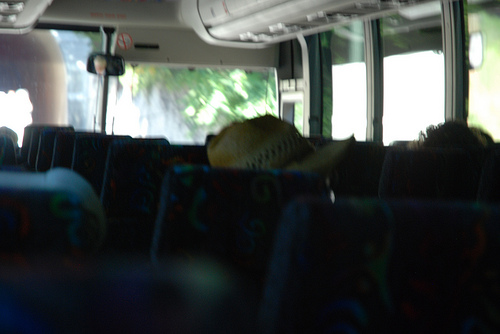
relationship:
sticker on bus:
[112, 30, 137, 54] [1, 1, 500, 331]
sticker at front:
[112, 30, 137, 54] [1, 1, 283, 146]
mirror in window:
[82, 23, 131, 81] [0, 19, 278, 149]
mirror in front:
[82, 23, 131, 81] [1, 1, 283, 146]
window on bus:
[0, 19, 278, 149] [1, 1, 500, 331]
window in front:
[0, 19, 278, 149] [1, 1, 283, 146]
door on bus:
[278, 78, 306, 138] [1, 1, 500, 331]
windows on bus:
[306, 0, 500, 148] [1, 1, 500, 331]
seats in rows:
[0, 123, 500, 333] [1, 1, 500, 331]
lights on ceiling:
[232, 2, 389, 48] [3, 0, 497, 50]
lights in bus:
[232, 2, 389, 48] [1, 1, 500, 331]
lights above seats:
[232, 2, 389, 48] [0, 123, 500, 333]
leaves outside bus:
[82, 19, 283, 140] [1, 1, 500, 331]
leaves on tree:
[82, 19, 283, 140] [0, 19, 278, 149]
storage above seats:
[177, 1, 314, 30] [0, 123, 500, 333]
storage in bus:
[177, 1, 314, 30] [1, 1, 500, 331]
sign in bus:
[112, 30, 137, 54] [1, 1, 500, 331]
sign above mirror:
[112, 30, 137, 54] [82, 23, 131, 81]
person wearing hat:
[200, 110, 360, 207] [203, 112, 356, 179]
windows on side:
[306, 0, 500, 148] [254, 0, 499, 179]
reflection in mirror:
[94, 55, 118, 75] [82, 23, 131, 81]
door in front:
[278, 78, 306, 138] [1, 1, 283, 146]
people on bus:
[201, 107, 499, 213] [1, 1, 500, 331]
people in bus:
[201, 107, 499, 213] [1, 1, 500, 331]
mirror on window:
[82, 23, 131, 81] [0, 19, 278, 149]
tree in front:
[115, 52, 276, 145] [1, 1, 283, 146]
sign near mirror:
[112, 30, 137, 54] [82, 23, 131, 81]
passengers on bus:
[201, 107, 499, 213] [1, 1, 500, 331]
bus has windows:
[1, 1, 500, 331] [306, 0, 500, 148]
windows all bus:
[306, 0, 500, 148] [1, 1, 500, 331]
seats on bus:
[0, 123, 500, 333] [1, 1, 500, 331]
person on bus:
[200, 110, 360, 207] [1, 1, 500, 331]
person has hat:
[200, 110, 360, 207] [203, 112, 356, 179]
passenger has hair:
[410, 113, 498, 158] [416, 115, 492, 151]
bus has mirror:
[1, 1, 500, 331] [82, 23, 131, 81]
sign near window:
[112, 30, 137, 54] [0, 19, 278, 149]